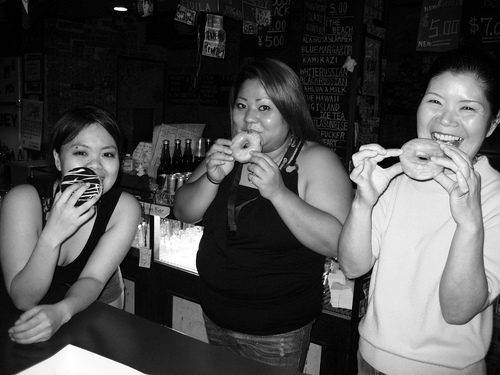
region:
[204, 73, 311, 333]
this is a lady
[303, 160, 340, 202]
the lady is light skinned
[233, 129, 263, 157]
this is a snack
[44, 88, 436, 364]
the ladies are three in number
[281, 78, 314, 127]
this is the hair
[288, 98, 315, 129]
the hair is long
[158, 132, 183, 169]
this is a bottle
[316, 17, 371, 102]
this is the wall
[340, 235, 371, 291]
the ankle is bent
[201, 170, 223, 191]
this is a wrist band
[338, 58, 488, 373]
this is a lady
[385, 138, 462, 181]
this is a doughnut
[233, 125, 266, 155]
the lady is eating the doughnut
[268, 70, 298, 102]
this is the hair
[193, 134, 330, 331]
the lady is fat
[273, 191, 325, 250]
this is the hand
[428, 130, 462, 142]
the lady is smiling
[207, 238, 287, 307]
the blouse is black in color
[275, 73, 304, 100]
the hair is long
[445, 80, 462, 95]
the lay is light skinned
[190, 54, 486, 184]
two women eating donuts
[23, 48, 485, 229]
three women eating donuts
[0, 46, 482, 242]
three people eating donuts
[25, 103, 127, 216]
women eating a donut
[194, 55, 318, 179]
woman eating a donut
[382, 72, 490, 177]
woman eating a donut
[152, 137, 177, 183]
dark brown bottles on shelf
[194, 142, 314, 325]
black tank top on woman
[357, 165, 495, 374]
white sweatshirt on woman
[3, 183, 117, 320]
black tank top on woman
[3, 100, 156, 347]
happy young Asian woman with a donut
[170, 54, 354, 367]
large young Asian woman eating a donut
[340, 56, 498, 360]
happy young Asian woman eating a donut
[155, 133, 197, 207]
three beer bottles sitting in a row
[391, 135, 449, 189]
plain donut being held by slim fingers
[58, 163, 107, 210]
chocolate donut with white glazed stripes being held by fingers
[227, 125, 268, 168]
plain donut being eaten and held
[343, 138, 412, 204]
hand with fingers being used like pincers to grasp a donut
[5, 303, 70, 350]
hand sitting at rest on a table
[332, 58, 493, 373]
laughing woman eating a donut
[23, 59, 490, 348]
three donut eating women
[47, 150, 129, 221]
a brown and white donut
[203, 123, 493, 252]
two glazed donuts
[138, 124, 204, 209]
three bottles of beer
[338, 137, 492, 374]
a white shirt on woman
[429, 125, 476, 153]
teeth in the mouth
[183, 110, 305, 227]
a lanyard around neck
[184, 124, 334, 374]
black top and jeans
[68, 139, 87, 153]
a dot on eyelid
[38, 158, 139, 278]
donut held in one hand